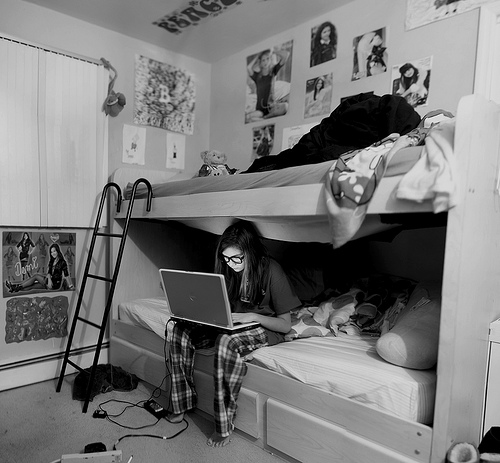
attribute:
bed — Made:
[123, 132, 454, 241]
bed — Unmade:
[115, 266, 432, 454]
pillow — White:
[374, 298, 439, 370]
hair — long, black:
[215, 218, 267, 309]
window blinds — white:
[1, 37, 116, 239]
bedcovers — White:
[106, 250, 438, 430]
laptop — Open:
[148, 201, 329, 425]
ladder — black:
[18, 184, 149, 316]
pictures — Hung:
[12, 210, 126, 412]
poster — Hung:
[347, 21, 390, 83]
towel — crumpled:
[67, 357, 134, 400]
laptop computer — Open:
[155, 267, 258, 331]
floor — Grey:
[25, 374, 200, 454]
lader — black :
[36, 169, 130, 420]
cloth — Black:
[226, 82, 442, 199]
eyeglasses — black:
[218, 250, 254, 265]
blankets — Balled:
[161, 109, 465, 239]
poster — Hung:
[388, 58, 434, 109]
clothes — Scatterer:
[261, 100, 461, 184]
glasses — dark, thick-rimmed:
[219, 239, 252, 276]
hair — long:
[177, 207, 298, 293]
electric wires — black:
[86, 377, 192, 451]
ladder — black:
[56, 174, 153, 414]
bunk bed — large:
[127, 92, 497, 456]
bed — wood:
[112, 96, 498, 224]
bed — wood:
[95, 298, 498, 461]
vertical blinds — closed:
[0, 32, 108, 227]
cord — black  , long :
[125, 412, 177, 450]